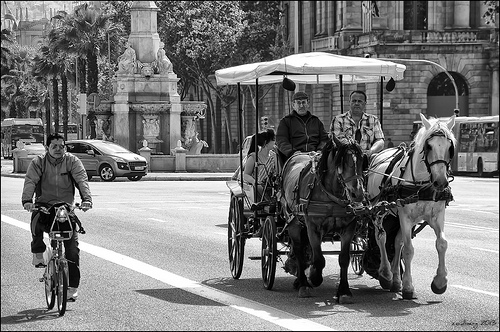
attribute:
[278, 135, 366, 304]
horse — black, brown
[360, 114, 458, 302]
horse — white, light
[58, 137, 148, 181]
car — parked, hatchback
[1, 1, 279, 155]
trees — tall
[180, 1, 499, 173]
building — detailed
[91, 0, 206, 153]
statue — concrete, detailed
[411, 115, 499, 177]
bus — parked